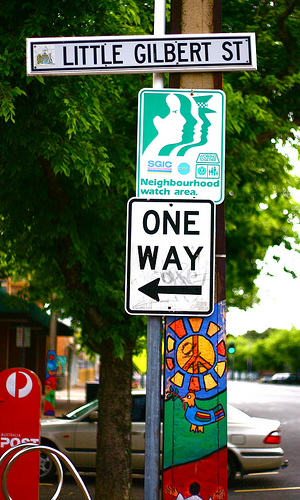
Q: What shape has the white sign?
A: Rectangle.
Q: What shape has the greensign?
A: Square.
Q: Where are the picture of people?
A: On green sign.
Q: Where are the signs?
A: On a pole.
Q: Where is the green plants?
A: Behind a pole.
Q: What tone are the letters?
A: Color black.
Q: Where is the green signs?
A: On the pole.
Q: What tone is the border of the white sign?
A: Black.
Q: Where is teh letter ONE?
A: On white sign.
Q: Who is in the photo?
A: Nobody.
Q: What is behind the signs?
A: A tree.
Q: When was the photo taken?
A: Daytime.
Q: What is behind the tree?
A: A car.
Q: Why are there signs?
A: To direct people.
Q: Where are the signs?
A: On a pole.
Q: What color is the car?
A: Tan.